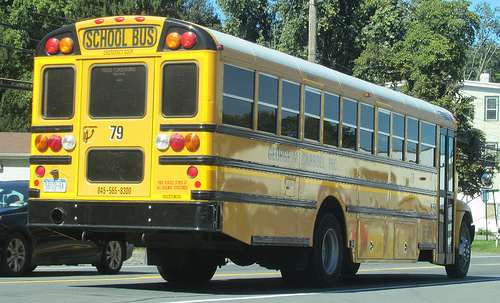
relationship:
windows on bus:
[41, 59, 438, 171] [26, 15, 475, 287]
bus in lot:
[26, 15, 475, 287] [1, 253, 499, 302]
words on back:
[84, 28, 153, 47] [26, 16, 200, 234]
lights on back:
[35, 17, 201, 189] [26, 16, 200, 234]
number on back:
[109, 124, 125, 142] [26, 16, 200, 234]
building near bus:
[381, 74, 499, 232] [26, 15, 475, 287]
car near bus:
[0, 180, 133, 276] [26, 15, 475, 287]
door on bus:
[438, 127, 456, 265] [26, 15, 475, 287]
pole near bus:
[307, 0, 319, 63] [26, 15, 475, 287]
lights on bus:
[35, 17, 201, 189] [26, 15, 475, 287]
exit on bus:
[76, 58, 154, 198] [26, 15, 475, 287]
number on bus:
[98, 187, 133, 196] [26, 15, 475, 287]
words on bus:
[84, 28, 153, 47] [26, 15, 475, 287]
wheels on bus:
[155, 216, 471, 286] [26, 15, 475, 287]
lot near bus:
[1, 253, 499, 302] [26, 15, 475, 287]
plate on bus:
[42, 178, 66, 193] [26, 15, 475, 287]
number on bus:
[109, 124, 125, 142] [26, 15, 475, 287]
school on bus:
[269, 147, 342, 172] [26, 15, 475, 287]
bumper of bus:
[26, 198, 220, 233] [26, 15, 475, 287]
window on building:
[482, 95, 499, 120] [381, 74, 499, 232]